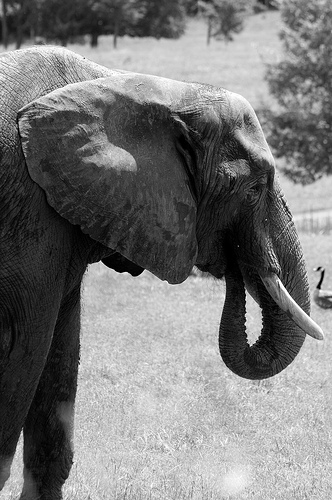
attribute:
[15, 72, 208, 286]
ear — very large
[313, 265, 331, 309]
fowl — water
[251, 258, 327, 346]
tusk — worn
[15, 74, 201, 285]
ears — large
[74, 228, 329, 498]
field — grassy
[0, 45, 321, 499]
elephant — gray, african, wrinkled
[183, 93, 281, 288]
head — top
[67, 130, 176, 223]
skin — rough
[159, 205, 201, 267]
mud — dry